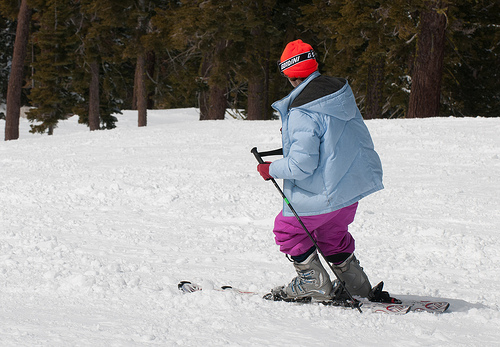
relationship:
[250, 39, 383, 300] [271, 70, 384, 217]
person wearing blue coat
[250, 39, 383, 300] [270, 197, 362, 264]
person wearing pants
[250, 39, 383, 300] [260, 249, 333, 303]
person wearing boot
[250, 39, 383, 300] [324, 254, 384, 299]
person wearing boot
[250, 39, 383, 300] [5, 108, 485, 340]
person skiing on mountain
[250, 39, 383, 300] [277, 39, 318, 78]
person wearing beanie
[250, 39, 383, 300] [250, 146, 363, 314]
person holding black pole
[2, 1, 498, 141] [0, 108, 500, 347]
background lining mountain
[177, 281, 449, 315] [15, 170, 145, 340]
long skis buried in snow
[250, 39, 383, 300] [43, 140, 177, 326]
person skiing on snow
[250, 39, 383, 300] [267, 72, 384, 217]
person wearing blue coat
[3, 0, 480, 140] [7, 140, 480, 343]
forest on side snow trail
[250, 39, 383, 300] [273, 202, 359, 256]
person with knees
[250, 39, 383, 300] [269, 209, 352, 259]
person bent on her knees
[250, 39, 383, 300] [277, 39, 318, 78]
person wearing a beanie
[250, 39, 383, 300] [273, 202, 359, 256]
person wearing knees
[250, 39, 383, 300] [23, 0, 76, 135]
person looking at tree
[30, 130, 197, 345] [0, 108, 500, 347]
ground covered in mountain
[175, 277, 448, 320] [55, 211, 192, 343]
long skis embedded in snow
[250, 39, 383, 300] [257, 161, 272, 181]
person wearing glove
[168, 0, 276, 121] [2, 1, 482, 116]
tree in background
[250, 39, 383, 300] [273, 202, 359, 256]
person in knees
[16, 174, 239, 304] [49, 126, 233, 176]
tracks in snow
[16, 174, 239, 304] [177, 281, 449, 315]
tracks from long skis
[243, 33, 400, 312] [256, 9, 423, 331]
person in clothes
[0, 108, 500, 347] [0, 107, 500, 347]
mountain on ground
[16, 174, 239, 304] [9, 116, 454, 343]
tracks on snow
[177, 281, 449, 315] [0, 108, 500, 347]
long skis in mountain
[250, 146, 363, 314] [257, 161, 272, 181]
black pole in glove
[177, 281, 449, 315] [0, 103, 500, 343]
long skis covered in snow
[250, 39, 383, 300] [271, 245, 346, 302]
person wearing boot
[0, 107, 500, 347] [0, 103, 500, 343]
ground covered in snow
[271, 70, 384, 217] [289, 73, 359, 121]
blue coat has hood